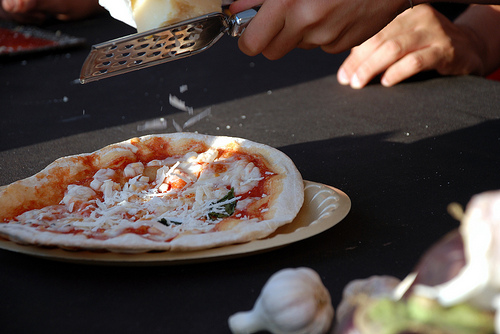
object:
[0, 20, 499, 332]
table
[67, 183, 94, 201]
garlic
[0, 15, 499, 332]
tablecloth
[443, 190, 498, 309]
garlic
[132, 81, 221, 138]
garlic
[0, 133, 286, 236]
grated cheese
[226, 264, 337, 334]
garlic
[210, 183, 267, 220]
leaf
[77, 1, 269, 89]
grater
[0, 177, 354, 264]
plate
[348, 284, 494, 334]
veggies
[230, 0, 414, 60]
hand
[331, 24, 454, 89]
fingers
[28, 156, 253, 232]
cheese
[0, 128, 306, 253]
pizza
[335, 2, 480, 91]
hand